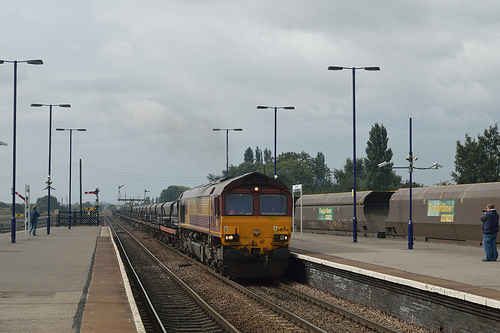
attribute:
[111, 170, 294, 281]
train — pulling in, yellow, large, industrial, metal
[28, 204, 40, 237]
person — standing on the side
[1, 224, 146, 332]
platform — in the station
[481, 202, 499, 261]
man — standing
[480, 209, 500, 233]
jacket — blue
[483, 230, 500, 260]
jeans — blue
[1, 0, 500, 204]
sky — cloudy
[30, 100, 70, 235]
street lamp — for light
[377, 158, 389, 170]
security camera — white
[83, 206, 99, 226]
stand — yellow